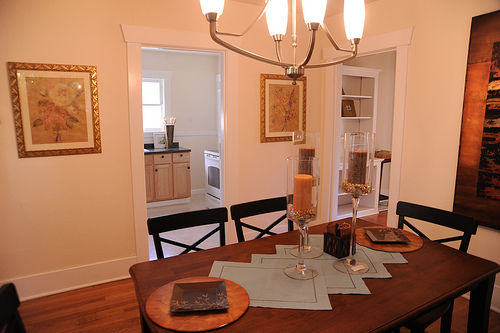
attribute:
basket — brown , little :
[323, 219, 358, 256]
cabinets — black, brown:
[147, 151, 190, 205]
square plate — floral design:
[165, 278, 235, 319]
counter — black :
[307, 238, 428, 323]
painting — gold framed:
[2, 59, 106, 154]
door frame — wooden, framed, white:
[120, 21, 249, 262]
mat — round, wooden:
[165, 274, 235, 318]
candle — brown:
[337, 148, 380, 187]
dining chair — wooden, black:
[391, 197, 483, 331]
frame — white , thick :
[388, 40, 408, 192]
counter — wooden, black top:
[145, 143, 192, 154]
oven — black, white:
[202, 148, 222, 207]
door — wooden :
[132, 47, 233, 259]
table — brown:
[374, 283, 447, 329]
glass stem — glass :
[287, 225, 317, 280]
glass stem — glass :
[294, 217, 320, 257]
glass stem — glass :
[327, 190, 369, 275]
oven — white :
[201, 147, 224, 210]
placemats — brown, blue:
[205, 222, 410, 311]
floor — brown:
[58, 295, 105, 330]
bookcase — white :
[336, 69, 376, 215]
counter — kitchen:
[141, 138, 193, 207]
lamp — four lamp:
[341, 0, 366, 43]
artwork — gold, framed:
[257, 68, 308, 139]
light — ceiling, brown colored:
[193, 2, 410, 86]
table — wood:
[64, 197, 494, 322]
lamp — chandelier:
[198, 7, 405, 95]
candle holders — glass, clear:
[268, 133, 388, 290]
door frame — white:
[122, 18, 244, 253]